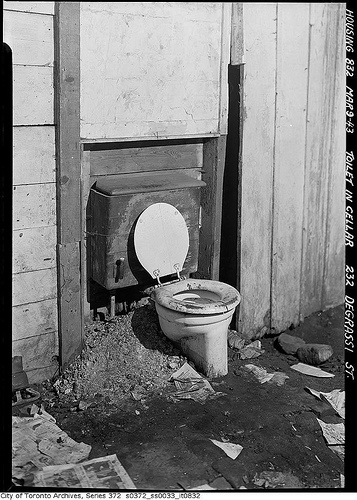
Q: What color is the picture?
A: Black and White.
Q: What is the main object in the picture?
A: Toilet.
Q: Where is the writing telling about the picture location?
A: Right side of pic.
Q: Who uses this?
A: People who lived at 232 Degrassi St.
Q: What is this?
A: A toilet.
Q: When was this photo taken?
A: On a sunny day.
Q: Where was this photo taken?
A: Outdoors around a toilet.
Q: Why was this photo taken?
A: To show the outdoor toilet.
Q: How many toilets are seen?
A: Just 1.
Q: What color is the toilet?
A: White.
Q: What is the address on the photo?
A: 232 Degrassi St.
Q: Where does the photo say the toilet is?
A: In the cellar.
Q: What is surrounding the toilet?
A: Dirt.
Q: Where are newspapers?
A: On ground.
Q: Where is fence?
A: Next to toilet.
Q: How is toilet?
A: Dirty.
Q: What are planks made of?
A: Wood.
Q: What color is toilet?
A: Gray.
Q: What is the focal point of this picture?
A: A toilet.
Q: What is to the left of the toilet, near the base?
A: A pile of dirt.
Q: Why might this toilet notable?
A: It is probably all that remains of this structure.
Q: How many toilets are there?
A: One.